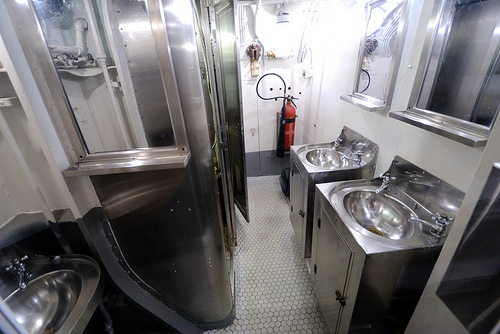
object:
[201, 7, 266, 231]
shower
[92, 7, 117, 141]
pipe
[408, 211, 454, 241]
faucet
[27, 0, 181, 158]
mirror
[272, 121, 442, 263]
sinks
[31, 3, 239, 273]
shower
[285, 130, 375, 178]
sink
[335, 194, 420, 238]
sink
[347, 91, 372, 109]
stell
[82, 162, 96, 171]
stell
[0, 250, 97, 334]
sink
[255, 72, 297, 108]
co2 hose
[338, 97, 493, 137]
shelves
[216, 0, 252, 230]
door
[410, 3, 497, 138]
mirror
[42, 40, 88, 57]
pipes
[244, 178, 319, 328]
floor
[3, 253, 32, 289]
faucet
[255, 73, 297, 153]
extinguisher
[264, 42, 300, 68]
valves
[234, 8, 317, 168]
wall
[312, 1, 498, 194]
wall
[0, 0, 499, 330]
bathroom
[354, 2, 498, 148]
mirrors